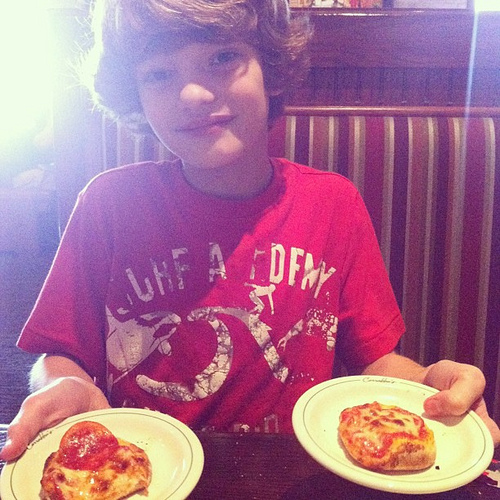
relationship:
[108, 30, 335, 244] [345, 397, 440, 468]
boy holding pizza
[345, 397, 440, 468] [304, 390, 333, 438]
pizza on plate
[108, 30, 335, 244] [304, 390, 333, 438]
boy holding plate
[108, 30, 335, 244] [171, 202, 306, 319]
boy wearing shirt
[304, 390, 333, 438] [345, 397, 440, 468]
plate with pizza